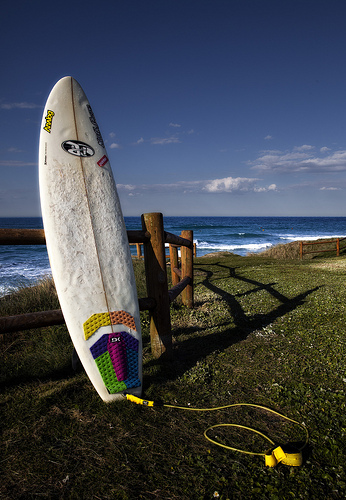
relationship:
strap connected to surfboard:
[125, 390, 311, 467] [39, 74, 144, 404]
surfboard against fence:
[39, 74, 144, 404] [5, 211, 196, 359]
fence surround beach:
[5, 211, 196, 359] [1, 236, 346, 367]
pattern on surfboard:
[59, 138, 96, 158] [39, 74, 144, 404]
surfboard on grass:
[39, 74, 144, 404] [1, 256, 342, 495]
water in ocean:
[5, 215, 345, 290] [0, 215, 345, 294]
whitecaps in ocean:
[3, 232, 343, 294] [0, 215, 345, 294]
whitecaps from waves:
[3, 232, 343, 294] [1, 215, 346, 297]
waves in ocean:
[1, 215, 346, 297] [0, 215, 345, 294]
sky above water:
[1, 1, 344, 215] [5, 215, 345, 290]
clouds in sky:
[3, 101, 345, 198] [1, 1, 344, 215]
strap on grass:
[125, 390, 311, 467] [1, 256, 342, 495]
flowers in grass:
[59, 277, 345, 500] [1, 256, 342, 495]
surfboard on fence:
[39, 74, 144, 404] [5, 211, 196, 359]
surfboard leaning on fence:
[39, 74, 144, 404] [5, 211, 196, 359]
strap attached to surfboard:
[125, 390, 311, 467] [39, 74, 144, 404]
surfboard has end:
[39, 74, 144, 404] [69, 309, 146, 402]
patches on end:
[84, 310, 142, 396] [69, 309, 146, 402]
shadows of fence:
[142, 255, 326, 383] [5, 211, 196, 359]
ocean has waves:
[0, 215, 345, 294] [1, 215, 346, 297]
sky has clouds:
[1, 1, 344, 215] [3, 101, 345, 198]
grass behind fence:
[1, 256, 342, 495] [5, 211, 196, 359]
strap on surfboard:
[125, 390, 311, 467] [39, 74, 144, 404]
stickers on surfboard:
[42, 100, 110, 168] [39, 74, 144, 404]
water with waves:
[5, 215, 345, 290] [1, 215, 346, 297]